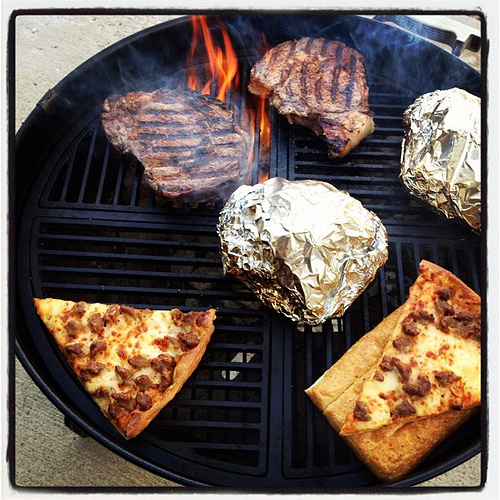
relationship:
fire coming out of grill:
[183, 14, 245, 106] [17, 15, 487, 490]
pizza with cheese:
[338, 260, 485, 437] [423, 330, 484, 391]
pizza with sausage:
[338, 260, 485, 437] [393, 360, 430, 416]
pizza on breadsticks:
[338, 260, 485, 437] [313, 303, 470, 471]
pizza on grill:
[338, 260, 485, 437] [94, 209, 219, 269]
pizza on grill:
[31, 293, 219, 443] [94, 209, 219, 269]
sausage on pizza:
[180, 327, 201, 346] [31, 293, 219, 443]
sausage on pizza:
[171, 327, 201, 351] [29, 270, 235, 454]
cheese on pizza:
[119, 325, 164, 347] [31, 293, 219, 443]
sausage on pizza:
[124, 351, 153, 371] [31, 293, 219, 443]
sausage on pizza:
[87, 344, 106, 362] [31, 293, 219, 443]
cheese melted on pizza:
[152, 311, 168, 338] [31, 293, 219, 443]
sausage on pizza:
[375, 355, 418, 377] [338, 260, 485, 437]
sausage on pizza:
[403, 381, 435, 395] [338, 260, 485, 437]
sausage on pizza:
[388, 400, 417, 417] [338, 260, 485, 437]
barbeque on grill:
[96, 80, 257, 201] [17, 15, 487, 490]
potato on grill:
[235, 199, 370, 272] [148, 100, 413, 294]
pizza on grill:
[31, 293, 219, 443] [17, 15, 487, 490]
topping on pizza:
[88, 339, 110, 354] [31, 293, 219, 443]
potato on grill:
[216, 175, 389, 325] [17, 15, 487, 490]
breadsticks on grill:
[305, 258, 482, 478] [17, 15, 487, 490]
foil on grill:
[217, 176, 387, 325] [17, 15, 487, 490]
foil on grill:
[403, 74, 483, 252] [17, 15, 487, 490]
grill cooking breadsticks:
[17, 15, 487, 490] [27, 295, 215, 441]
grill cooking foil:
[17, 15, 487, 490] [217, 176, 387, 325]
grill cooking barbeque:
[17, 15, 487, 490] [96, 80, 257, 201]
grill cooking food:
[17, 15, 487, 490] [250, 35, 376, 167]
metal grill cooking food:
[255, 134, 333, 185] [99, 76, 329, 274]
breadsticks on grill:
[318, 340, 374, 415] [17, 15, 487, 490]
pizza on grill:
[338, 260, 485, 437] [17, 15, 487, 490]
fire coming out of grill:
[183, 14, 245, 106] [36, 30, 474, 476]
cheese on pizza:
[119, 325, 154, 368] [31, 293, 219, 443]